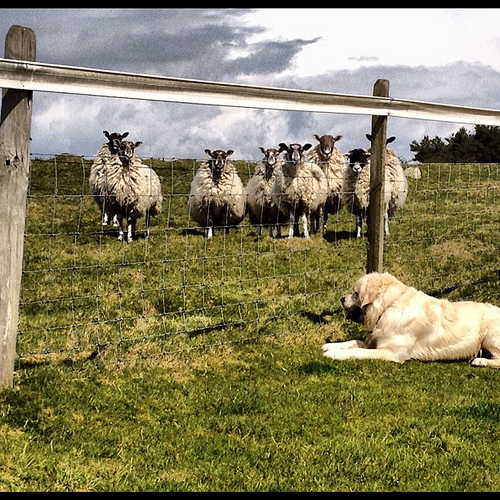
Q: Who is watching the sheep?
A: The dog.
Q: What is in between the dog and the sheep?
A: The fence.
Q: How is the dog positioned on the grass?
A: Laying down.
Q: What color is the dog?
A: Yellow.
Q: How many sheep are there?
A: 8.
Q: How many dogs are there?
A: 1.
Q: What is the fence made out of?
A: Wood and wire.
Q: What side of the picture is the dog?
A: Right side.